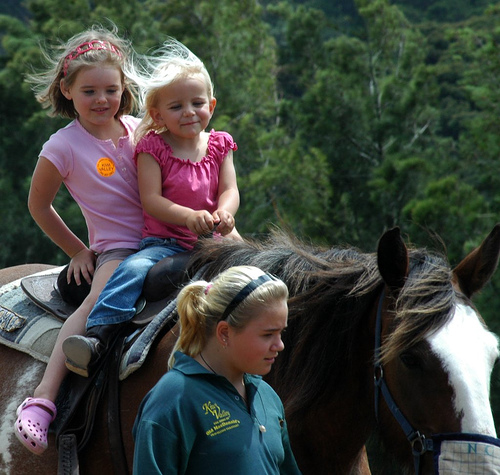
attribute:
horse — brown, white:
[3, 227, 498, 474]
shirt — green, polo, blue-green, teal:
[125, 352, 303, 470]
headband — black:
[220, 264, 279, 319]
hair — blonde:
[164, 264, 292, 366]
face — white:
[420, 302, 499, 474]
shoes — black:
[59, 327, 112, 379]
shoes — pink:
[12, 391, 64, 463]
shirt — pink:
[135, 129, 248, 248]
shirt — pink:
[41, 114, 154, 249]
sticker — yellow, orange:
[95, 154, 118, 178]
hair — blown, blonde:
[127, 34, 217, 147]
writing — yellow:
[201, 400, 241, 437]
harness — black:
[368, 281, 499, 472]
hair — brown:
[20, 17, 135, 121]